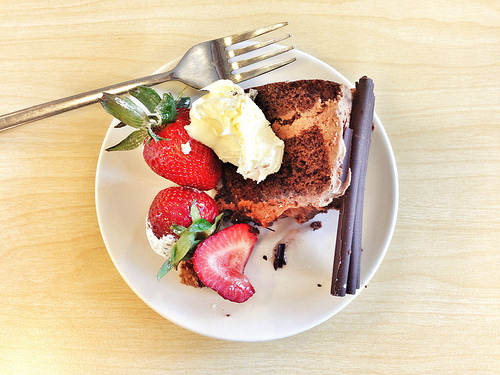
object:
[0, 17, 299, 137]
fork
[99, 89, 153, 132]
leaf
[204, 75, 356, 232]
cake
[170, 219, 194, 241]
green leaf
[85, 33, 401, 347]
plate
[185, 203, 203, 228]
green leaf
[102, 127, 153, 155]
green leaf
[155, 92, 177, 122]
leaf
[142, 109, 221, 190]
strawberry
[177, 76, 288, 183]
cream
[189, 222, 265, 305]
strawberries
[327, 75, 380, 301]
stick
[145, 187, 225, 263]
strawberry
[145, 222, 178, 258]
chantilly cream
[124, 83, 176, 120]
leaf